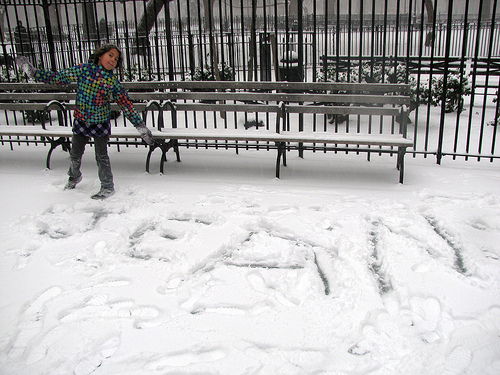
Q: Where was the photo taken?
A: It was taken at the park.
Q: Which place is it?
A: It is a park.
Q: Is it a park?
A: Yes, it is a park.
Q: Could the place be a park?
A: Yes, it is a park.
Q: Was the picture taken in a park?
A: Yes, it was taken in a park.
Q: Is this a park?
A: Yes, it is a park.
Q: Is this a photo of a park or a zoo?
A: It is showing a park.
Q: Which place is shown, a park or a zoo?
A: It is a park.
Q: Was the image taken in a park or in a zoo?
A: It was taken at a park.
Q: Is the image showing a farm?
A: No, the picture is showing a park.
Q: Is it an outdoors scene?
A: Yes, it is outdoors.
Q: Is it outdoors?
A: Yes, it is outdoors.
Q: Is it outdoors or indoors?
A: It is outdoors.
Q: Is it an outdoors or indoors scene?
A: It is outdoors.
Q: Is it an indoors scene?
A: No, it is outdoors.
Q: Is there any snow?
A: Yes, there is snow.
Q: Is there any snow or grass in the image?
A: Yes, there is snow.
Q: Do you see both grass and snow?
A: No, there is snow but no grass.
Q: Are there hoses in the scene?
A: No, there are no hoses.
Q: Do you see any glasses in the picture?
A: No, there are no glasses.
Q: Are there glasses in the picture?
A: No, there are no glasses.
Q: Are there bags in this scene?
A: No, there are no bags.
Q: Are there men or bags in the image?
A: No, there are no bags or men.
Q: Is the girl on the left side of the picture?
A: Yes, the girl is on the left of the image.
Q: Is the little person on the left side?
A: Yes, the girl is on the left of the image.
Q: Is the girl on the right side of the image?
A: No, the girl is on the left of the image.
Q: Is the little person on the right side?
A: No, the girl is on the left of the image.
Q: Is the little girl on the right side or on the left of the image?
A: The girl is on the left of the image.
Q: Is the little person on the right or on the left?
A: The girl is on the left of the image.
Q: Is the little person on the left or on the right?
A: The girl is on the left of the image.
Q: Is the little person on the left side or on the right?
A: The girl is on the left of the image.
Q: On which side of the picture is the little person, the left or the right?
A: The girl is on the left of the image.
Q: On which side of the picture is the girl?
A: The girl is on the left of the image.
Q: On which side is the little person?
A: The girl is on the left of the image.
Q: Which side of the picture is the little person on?
A: The girl is on the left of the image.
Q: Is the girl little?
A: Yes, the girl is little.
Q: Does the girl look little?
A: Yes, the girl is little.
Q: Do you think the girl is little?
A: Yes, the girl is little.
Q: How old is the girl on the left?
A: The girl is little.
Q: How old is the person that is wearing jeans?
A: The girl is little.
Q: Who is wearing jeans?
A: The girl is wearing jeans.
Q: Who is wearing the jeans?
A: The girl is wearing jeans.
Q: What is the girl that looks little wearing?
A: The girl is wearing jeans.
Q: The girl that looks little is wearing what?
A: The girl is wearing jeans.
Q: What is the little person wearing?
A: The girl is wearing jeans.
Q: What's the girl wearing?
A: The girl is wearing jeans.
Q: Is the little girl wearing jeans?
A: Yes, the girl is wearing jeans.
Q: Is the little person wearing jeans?
A: Yes, the girl is wearing jeans.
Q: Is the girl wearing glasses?
A: No, the girl is wearing jeans.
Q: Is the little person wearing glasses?
A: No, the girl is wearing jeans.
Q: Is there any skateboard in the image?
A: No, there are no skateboards.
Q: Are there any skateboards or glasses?
A: No, there are no skateboards or glasses.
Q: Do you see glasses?
A: No, there are no glasses.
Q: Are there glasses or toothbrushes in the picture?
A: No, there are no glasses or toothbrushes.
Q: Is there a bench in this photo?
A: Yes, there is a bench.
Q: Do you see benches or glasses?
A: Yes, there is a bench.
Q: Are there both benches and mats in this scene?
A: No, there is a bench but no mats.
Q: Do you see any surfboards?
A: No, there are no surfboards.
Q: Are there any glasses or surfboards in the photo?
A: No, there are no surfboards or glasses.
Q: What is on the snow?
A: The bench is on the snow.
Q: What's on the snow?
A: The bench is on the snow.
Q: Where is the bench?
A: The bench is on the snow.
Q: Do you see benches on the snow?
A: Yes, there is a bench on the snow.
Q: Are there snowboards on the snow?
A: No, there is a bench on the snow.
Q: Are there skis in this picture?
A: No, there are no skis.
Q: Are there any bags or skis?
A: No, there are no skis or bags.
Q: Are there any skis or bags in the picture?
A: No, there are no skis or bags.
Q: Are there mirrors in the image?
A: No, there are no mirrors.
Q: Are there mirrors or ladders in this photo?
A: No, there are no mirrors or ladders.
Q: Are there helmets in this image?
A: No, there are no helmets.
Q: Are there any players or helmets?
A: No, there are no helmets or players.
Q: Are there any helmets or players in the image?
A: No, there are no helmets or players.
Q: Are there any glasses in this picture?
A: No, there are no glasses.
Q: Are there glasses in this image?
A: No, there are no glasses.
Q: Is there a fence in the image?
A: Yes, there is a fence.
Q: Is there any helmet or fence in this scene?
A: Yes, there is a fence.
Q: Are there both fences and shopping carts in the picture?
A: No, there is a fence but no shopping carts.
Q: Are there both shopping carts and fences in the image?
A: No, there is a fence but no shopping carts.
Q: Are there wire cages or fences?
A: Yes, there is a wire fence.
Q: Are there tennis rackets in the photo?
A: No, there are no tennis rackets.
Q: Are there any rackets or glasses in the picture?
A: No, there are no rackets or glasses.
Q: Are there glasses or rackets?
A: No, there are no rackets or glasses.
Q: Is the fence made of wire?
A: Yes, the fence is made of wire.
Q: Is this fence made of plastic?
A: No, the fence is made of wire.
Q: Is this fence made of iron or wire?
A: The fence is made of wire.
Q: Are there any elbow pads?
A: No, there are no elbow pads.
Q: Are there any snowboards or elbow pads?
A: No, there are no elbow pads or snowboards.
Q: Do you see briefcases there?
A: No, there are no briefcases.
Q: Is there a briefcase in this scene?
A: No, there are no briefcases.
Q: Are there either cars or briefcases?
A: No, there are no briefcases or cars.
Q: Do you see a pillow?
A: No, there are no pillows.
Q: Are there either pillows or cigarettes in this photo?
A: No, there are no pillows or cigarettes.